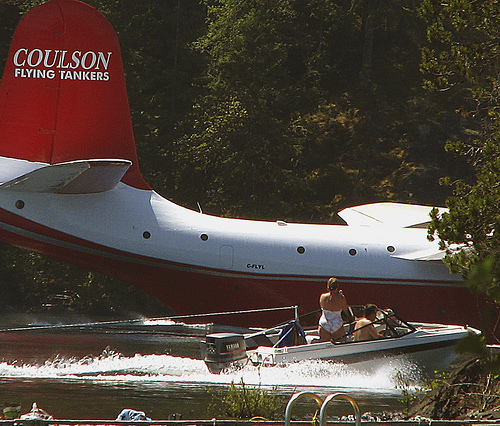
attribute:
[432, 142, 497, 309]
branches — tree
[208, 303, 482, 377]
boat — white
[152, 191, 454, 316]
plane — large , red, white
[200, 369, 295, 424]
bush — green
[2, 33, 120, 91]
logo — airplane company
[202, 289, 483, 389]
boat — white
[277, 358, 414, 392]
water spray — white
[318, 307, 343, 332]
bathing suit — white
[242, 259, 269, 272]
letters — black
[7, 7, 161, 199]
tail — red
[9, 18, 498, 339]
plane — white, red, huge 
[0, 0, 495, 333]
airplane — red, white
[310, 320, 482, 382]
stripe — dark 